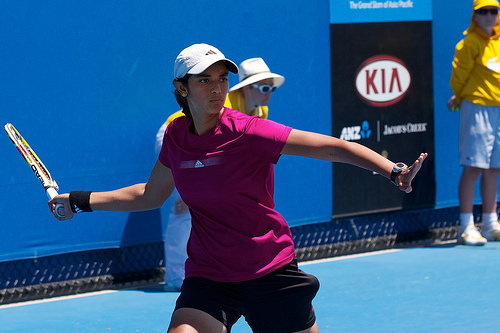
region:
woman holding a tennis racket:
[7, 29, 387, 299]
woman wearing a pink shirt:
[7, 30, 351, 320]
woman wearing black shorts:
[36, 40, 423, 322]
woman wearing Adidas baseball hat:
[49, 33, 431, 315]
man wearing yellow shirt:
[172, 39, 287, 143]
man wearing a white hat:
[142, 40, 316, 147]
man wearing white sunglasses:
[126, 28, 316, 150]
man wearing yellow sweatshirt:
[448, 5, 496, 248]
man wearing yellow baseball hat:
[457, 1, 497, 244]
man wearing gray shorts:
[454, 4, 499, 241]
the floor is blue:
[343, 268, 441, 326]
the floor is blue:
[359, 267, 396, 309]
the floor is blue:
[385, 261, 426, 319]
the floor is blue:
[365, 255, 476, 323]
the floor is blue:
[363, 291, 413, 318]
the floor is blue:
[366, 244, 430, 299]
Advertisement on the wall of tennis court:
[342, 49, 420, 107]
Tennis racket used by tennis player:
[0, 108, 72, 225]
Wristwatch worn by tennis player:
[392, 154, 407, 197]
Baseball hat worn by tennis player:
[172, 39, 254, 86]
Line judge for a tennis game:
[231, 41, 288, 96]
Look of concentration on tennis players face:
[167, 62, 235, 119]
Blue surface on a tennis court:
[340, 281, 443, 328]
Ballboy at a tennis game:
[442, 0, 498, 253]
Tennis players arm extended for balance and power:
[255, 109, 439, 205]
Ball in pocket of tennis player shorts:
[285, 249, 332, 324]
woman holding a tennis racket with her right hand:
[3, 43, 237, 279]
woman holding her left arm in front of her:
[178, 50, 438, 199]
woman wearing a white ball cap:
[165, 40, 237, 121]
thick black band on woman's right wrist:
[63, 178, 100, 218]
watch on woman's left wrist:
[377, 145, 411, 187]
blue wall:
[5, 0, 499, 304]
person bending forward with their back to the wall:
[146, 50, 296, 290]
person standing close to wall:
[431, 0, 498, 258]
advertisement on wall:
[289, 2, 464, 214]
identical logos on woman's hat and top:
[182, 41, 237, 188]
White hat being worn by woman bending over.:
[225, 50, 295, 115]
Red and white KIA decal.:
[350, 47, 415, 102]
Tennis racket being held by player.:
[2, 100, 72, 222]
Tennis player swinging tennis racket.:
[5, 32, 425, 327]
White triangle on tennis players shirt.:
[190, 151, 202, 171]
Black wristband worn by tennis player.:
[66, 185, 92, 216]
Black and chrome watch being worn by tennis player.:
[382, 156, 407, 191]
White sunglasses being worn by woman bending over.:
[245, 75, 276, 90]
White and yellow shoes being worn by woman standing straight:
[451, 220, 496, 245]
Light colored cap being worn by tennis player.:
[166, 40, 241, 80]